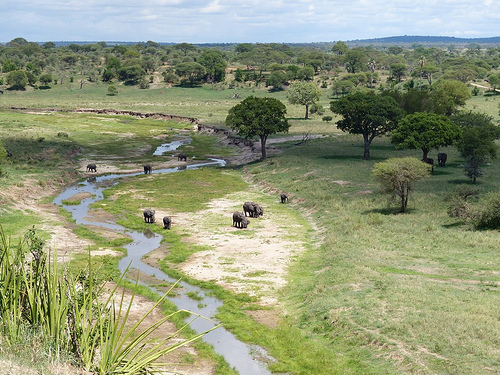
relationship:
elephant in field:
[142, 206, 159, 225] [3, 88, 499, 373]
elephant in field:
[276, 192, 291, 203] [3, 88, 499, 373]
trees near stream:
[223, 82, 499, 188] [57, 170, 274, 373]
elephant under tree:
[435, 152, 450, 168] [390, 109, 459, 169]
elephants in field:
[232, 200, 265, 231] [3, 88, 499, 373]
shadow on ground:
[363, 203, 414, 216] [3, 88, 499, 374]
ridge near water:
[1, 168, 88, 232] [55, 173, 107, 207]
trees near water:
[226, 94, 290, 167] [55, 173, 107, 207]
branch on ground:
[275, 130, 321, 153] [3, 88, 499, 374]